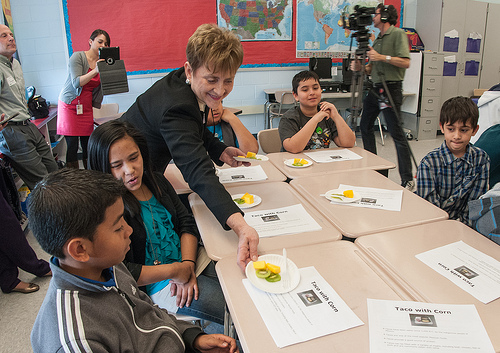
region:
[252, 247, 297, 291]
plate with kiwi and pineapple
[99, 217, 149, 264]
face of small child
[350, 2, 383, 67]
camera on tripod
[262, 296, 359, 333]
paper with menu on table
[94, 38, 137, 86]
iPad recording lady setting plate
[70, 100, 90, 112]
name tag of lady in distance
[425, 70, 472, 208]
little kid with plaid shirt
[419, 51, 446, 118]
cabinet with drawers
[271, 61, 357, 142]
little kid smiling at lady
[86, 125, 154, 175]
upper face of little girl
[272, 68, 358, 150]
boy wearing t-shirt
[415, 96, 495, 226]
boy in plaid shirt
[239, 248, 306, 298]
paper plate with kiwi slices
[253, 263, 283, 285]
two slices of kiwi fruit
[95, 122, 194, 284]
girl with teal shirt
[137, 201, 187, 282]
ruffle trim on girl's shirt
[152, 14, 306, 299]
woman handing plate of fruit to a child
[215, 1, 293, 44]
wall map of the United States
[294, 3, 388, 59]
wall map of the world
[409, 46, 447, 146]
grey four drawer filing cabinet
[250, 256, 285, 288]
Fruit on a white plate.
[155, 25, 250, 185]
Women in black suit.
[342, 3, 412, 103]
Cameraman filming people.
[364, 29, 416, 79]
Green shirt on cameraman.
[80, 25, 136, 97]
Women holding computer tablet.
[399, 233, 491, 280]
Papers sitting on desk.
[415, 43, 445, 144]
Draws closed shut.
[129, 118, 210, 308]
Women wearing green shirt.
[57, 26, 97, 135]
Women wearing red dress.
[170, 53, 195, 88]
Silver earrings in women's ear.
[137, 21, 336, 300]
lady serving plate with food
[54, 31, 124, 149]
lady wearing red dress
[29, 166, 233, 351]
gray jacket with white stripes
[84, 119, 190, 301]
girl wearing turquoise shirt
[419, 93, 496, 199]
boy wearing blue and gray plaid shirt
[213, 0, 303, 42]
map hanging on wall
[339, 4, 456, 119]
man operating movie camera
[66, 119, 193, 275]
girl wearing black sweater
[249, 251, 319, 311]
plate with yellow food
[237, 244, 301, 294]
white plate with green food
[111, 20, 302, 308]
A woman handing out meals to a young kid.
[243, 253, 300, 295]
A delicious sample of kiwi and pineapple.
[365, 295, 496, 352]
A sheet of paper saying Taco with Corn.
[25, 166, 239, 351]
A young boy wearing a grey sweater.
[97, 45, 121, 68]
An iPad used to take pictures of everyone.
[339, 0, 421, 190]
A cameraman filming the entire scene.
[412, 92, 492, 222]
A young pre-teen little boy.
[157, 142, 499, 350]
Six small tables stuck together to make a big one.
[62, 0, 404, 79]
A red board with two maps in it.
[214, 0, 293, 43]
A map of the United States of America.